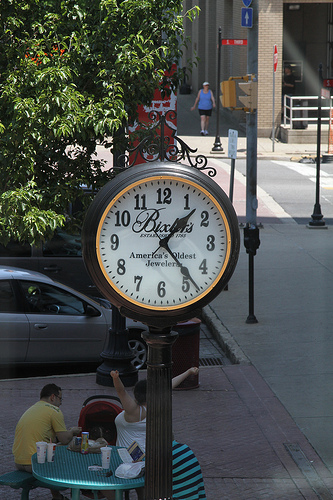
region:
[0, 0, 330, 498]
Daytime on the street.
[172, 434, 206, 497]
The shirt has blue and black stripes.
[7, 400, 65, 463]
The man is wearing a yellow shirt.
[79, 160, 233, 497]
A clock is on a pole.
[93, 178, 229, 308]
The clock has a white face with black numbers.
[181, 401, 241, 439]
Bricks are on the sidewalk.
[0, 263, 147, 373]
The parked car is silver colored.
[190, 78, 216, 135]
A person is walking down the street.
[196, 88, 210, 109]
The person is wearing a blue tank top.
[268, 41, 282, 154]
The stop sign is on a pole.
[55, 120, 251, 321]
Clock on the side walk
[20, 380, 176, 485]
Man and woman sitting at table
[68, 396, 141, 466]
Baby inside of stroller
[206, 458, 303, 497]
Crack in the pavement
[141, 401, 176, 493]
metal pole under clock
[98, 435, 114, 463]
Disposable cup on table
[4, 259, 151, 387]
Car parked in parking space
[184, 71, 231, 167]
Woman walking on sidewalk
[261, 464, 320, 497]
Light shining on ground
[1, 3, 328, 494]
A city sidewalk scene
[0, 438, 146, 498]
A table is on the sidewalk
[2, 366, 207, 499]
People are sitting around the table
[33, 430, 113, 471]
Beverages are on the table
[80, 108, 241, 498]
A clock is on the sidewalk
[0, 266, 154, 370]
A silver car is parked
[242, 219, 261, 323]
This is a parking meter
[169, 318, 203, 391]
A garbage can is on the sidewalk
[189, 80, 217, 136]
A person is walking on the sidewalk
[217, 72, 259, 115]
These are crosswalk signal lights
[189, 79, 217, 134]
woman in a blue top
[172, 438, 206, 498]
person in a striped shirt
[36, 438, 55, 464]
drinks sitting on a table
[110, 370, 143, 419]
womans' arm lifted in the air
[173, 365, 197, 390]
right arm of woman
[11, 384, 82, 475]
man in a yellow shirt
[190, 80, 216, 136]
woman walking in the shade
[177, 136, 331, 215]
an area of sunshine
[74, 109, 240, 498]
a metal clock on a pole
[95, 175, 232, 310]
gold circle around the face of the clock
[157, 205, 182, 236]
part of a glass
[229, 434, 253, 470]
part of a flopor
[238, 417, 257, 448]
part of a floor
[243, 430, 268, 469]
part of a floor